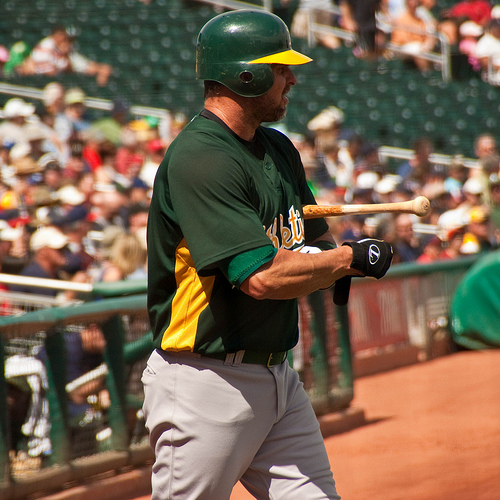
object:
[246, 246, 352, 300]
arm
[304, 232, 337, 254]
bat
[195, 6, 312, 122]
man's head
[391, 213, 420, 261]
man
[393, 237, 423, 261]
shirt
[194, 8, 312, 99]
green/yellow helmet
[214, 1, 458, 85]
rail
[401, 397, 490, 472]
dirt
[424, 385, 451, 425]
ground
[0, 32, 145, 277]
fans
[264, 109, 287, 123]
beard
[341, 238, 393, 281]
glove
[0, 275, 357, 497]
fence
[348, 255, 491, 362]
fence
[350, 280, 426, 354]
sign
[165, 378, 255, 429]
pocket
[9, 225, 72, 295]
man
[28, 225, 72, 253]
hat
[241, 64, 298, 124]
face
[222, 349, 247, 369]
loops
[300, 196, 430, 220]
baseball bat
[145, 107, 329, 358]
shirt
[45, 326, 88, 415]
padding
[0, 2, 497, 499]
stadium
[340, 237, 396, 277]
hand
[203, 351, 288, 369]
belt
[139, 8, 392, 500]
man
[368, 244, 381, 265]
design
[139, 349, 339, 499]
pants